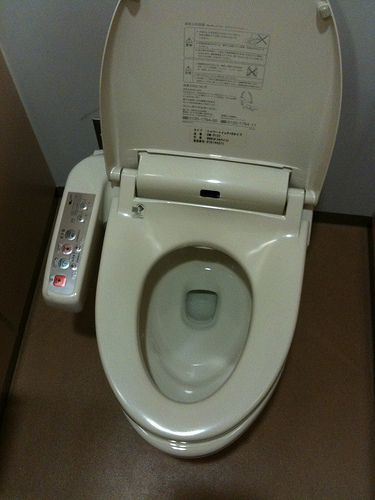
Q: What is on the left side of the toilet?
A: Remote control.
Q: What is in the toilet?
A: Water.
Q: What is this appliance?
A: Toilet.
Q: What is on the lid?
A: Direction sticker.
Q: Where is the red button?
A: Panel on left of toilet.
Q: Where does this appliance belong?
A: Bathroom.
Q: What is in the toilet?
A: Water.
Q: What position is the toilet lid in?
A: The up position.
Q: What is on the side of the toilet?
A: A remote control.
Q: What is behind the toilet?
A: A white wall.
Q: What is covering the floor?
A: Brown paint.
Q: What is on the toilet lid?
A: Instructions.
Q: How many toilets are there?
A: One.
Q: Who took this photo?
A: A journalist.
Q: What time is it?
A: Noon.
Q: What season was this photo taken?
A: Winter.